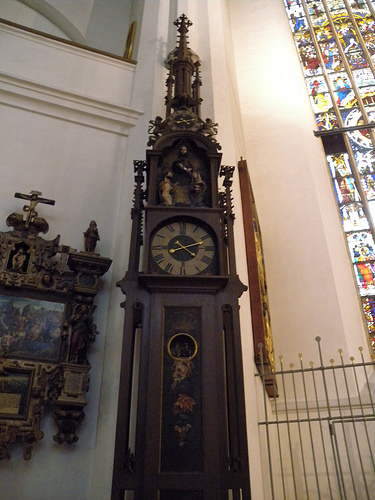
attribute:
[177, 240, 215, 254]
mark — hour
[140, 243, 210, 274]
numbers — roman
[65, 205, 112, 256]
statue — virgin mary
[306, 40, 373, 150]
window — stained glass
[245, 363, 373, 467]
grill — metal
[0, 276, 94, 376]
picture — hanging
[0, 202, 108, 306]
frame — wood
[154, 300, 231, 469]
design — rectangular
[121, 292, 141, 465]
slot — rectangular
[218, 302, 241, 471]
slot — rectangular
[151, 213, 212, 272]
clock — tall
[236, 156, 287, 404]
picture — framed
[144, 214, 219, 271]
clock — grandfather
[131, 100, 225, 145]
images — religious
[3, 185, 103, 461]
religions painting — framed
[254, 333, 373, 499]
decoration — ornate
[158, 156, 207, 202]
statues — religious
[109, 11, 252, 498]
clock — decorative, dark, wooden, ornate, grandfather, floor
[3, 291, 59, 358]
portrait — religious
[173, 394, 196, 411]
leaves — painted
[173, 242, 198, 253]
hand — gold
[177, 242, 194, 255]
hand — gold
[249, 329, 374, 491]
bar — metal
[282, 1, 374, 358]
windows — stained glass